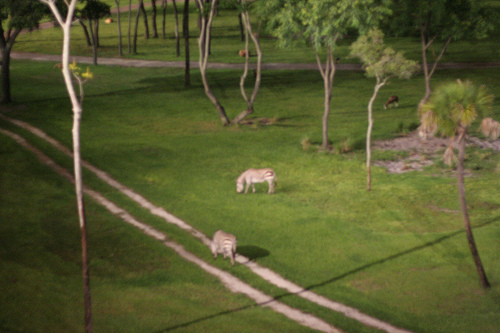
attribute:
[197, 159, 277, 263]
zebras — grazing, white, black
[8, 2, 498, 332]
grass — green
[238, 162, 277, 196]
zebra — grazing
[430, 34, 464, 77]
branch — brown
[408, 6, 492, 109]
tree — green, skinny, tall, thin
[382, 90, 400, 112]
animal — white, brown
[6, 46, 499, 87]
road — narrow, cement, grey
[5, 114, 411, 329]
tracks — parallel, white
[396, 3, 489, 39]
leaves — green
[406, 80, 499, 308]
tree — yellow, narrow, tall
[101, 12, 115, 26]
rock — large, beige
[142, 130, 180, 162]
grass — green, greem